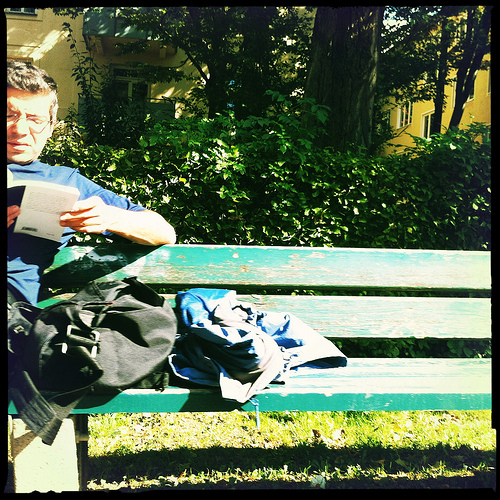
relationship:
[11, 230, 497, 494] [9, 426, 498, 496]
bench has shadow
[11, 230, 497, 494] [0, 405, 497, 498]
bench on ground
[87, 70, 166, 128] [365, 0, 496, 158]
wndow on house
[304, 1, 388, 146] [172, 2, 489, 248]
trunk of a tree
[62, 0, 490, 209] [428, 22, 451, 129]
tree has trunk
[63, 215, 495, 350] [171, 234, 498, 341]
rail of a wood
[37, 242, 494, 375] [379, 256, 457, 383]
rail of a wood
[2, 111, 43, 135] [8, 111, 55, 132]
glasses on face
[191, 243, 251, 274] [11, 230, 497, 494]
paint on bench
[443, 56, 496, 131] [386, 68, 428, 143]
paint on wall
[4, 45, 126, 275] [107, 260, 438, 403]
man on bench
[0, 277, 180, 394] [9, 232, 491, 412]
bag on bench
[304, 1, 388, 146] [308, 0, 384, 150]
trunk on tree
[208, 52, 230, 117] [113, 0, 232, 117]
trunk of tree